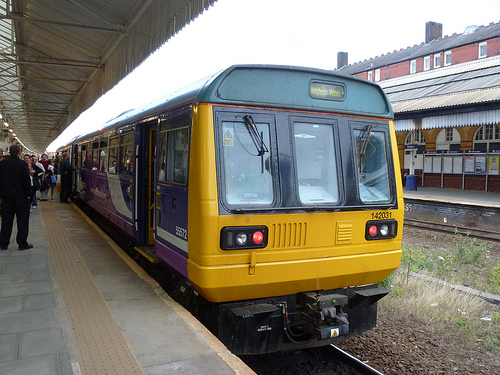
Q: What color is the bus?
A: Yellow.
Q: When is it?
A: Day time.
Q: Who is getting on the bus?
A: Passengers.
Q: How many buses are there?
A: One.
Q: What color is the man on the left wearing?
A: Black.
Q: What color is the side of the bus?
A: Blue.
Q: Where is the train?
A: At the station.